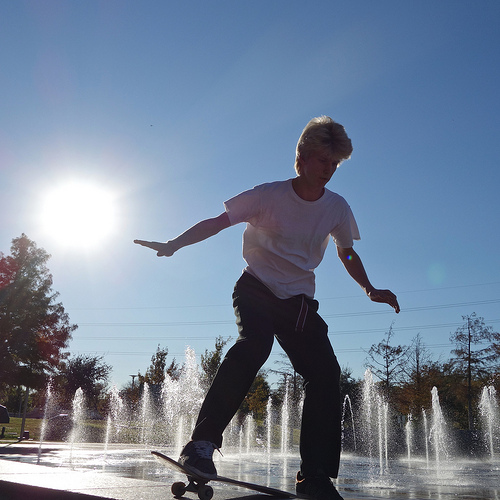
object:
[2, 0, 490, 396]
sky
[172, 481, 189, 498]
wheels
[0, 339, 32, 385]
leaves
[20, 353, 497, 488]
water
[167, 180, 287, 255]
arms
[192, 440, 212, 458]
laces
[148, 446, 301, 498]
skateboard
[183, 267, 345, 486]
pants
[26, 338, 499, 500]
fountain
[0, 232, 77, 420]
tree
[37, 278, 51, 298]
leaves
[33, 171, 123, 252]
sun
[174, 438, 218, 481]
shoe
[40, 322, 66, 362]
leaves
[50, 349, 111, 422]
tree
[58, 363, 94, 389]
leaves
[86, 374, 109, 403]
leaves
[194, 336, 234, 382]
tree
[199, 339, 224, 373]
leaves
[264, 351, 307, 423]
tree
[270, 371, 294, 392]
leaves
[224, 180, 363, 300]
shirt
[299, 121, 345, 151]
hair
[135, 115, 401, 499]
man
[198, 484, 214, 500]
wheels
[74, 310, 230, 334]
power lines